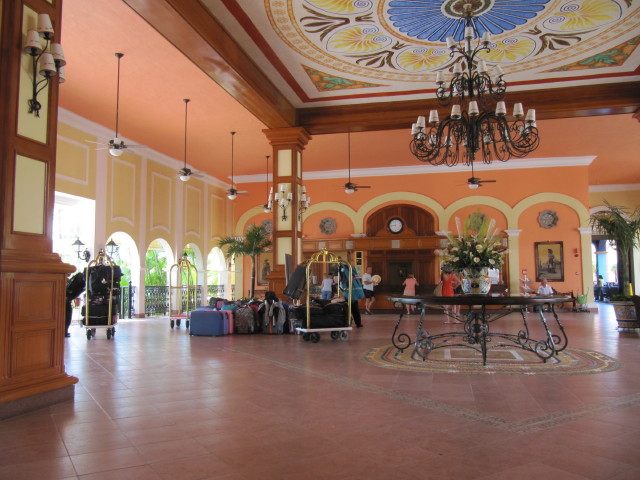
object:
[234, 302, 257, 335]
suitcase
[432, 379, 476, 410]
tile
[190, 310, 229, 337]
suitcase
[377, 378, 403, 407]
tile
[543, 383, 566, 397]
tile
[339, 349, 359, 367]
tile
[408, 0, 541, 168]
chandelier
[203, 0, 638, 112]
ceiling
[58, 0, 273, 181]
ceiling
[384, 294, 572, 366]
round table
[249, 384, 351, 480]
red tile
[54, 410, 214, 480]
red tile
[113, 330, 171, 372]
red tile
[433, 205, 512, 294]
plant